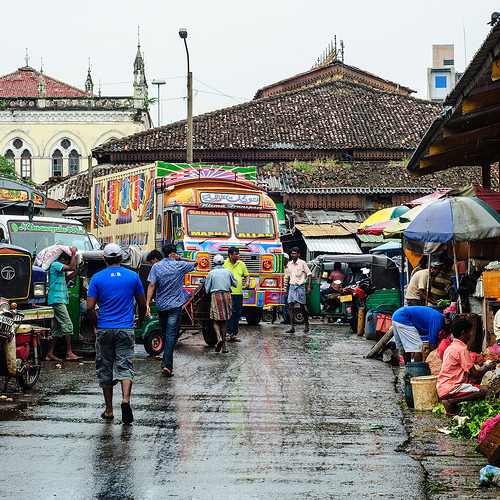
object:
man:
[90, 241, 146, 422]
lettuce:
[463, 392, 482, 407]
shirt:
[224, 258, 248, 294]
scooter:
[0, 305, 57, 388]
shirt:
[86, 265, 146, 329]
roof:
[0, 64, 96, 96]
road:
[156, 308, 356, 494]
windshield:
[189, 210, 226, 228]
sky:
[260, 17, 307, 67]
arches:
[1, 128, 40, 158]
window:
[57, 159, 65, 177]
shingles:
[325, 109, 337, 128]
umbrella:
[403, 193, 499, 242]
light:
[180, 27, 188, 40]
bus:
[88, 162, 288, 324]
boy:
[435, 318, 492, 414]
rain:
[276, 358, 339, 405]